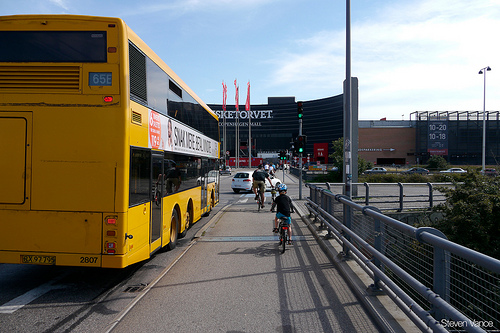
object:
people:
[264, 179, 296, 255]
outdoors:
[197, 69, 344, 329]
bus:
[0, 11, 225, 272]